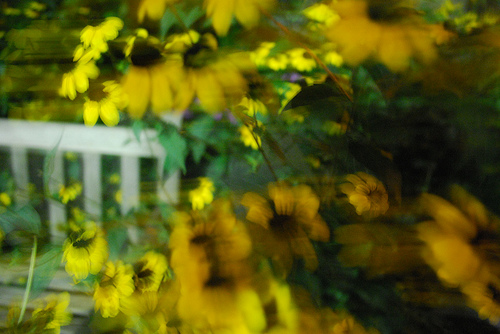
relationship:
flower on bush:
[57, 48, 98, 93] [57, 3, 497, 331]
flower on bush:
[70, 15, 122, 59] [57, 3, 497, 331]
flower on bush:
[62, 227, 107, 283] [57, 3, 497, 331]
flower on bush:
[238, 182, 327, 272] [57, 3, 497, 331]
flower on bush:
[340, 171, 388, 220] [57, 3, 497, 331]